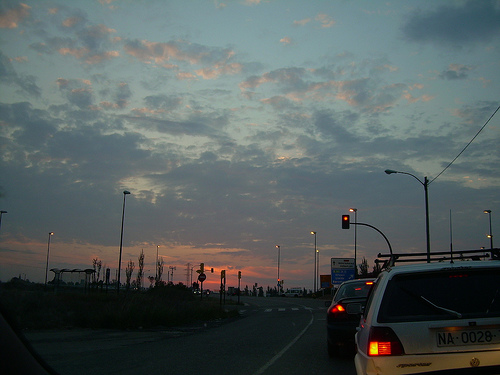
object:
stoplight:
[211, 268, 214, 274]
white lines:
[305, 307, 313, 310]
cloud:
[0, 0, 500, 293]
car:
[353, 260, 500, 375]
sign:
[198, 273, 206, 282]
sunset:
[163, 233, 263, 292]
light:
[343, 216, 349, 221]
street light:
[50, 232, 53, 236]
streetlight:
[123, 190, 130, 194]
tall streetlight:
[117, 194, 125, 294]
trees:
[155, 255, 164, 289]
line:
[252, 310, 314, 375]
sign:
[331, 258, 356, 285]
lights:
[310, 231, 315, 235]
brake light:
[368, 340, 391, 356]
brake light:
[331, 304, 345, 314]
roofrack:
[373, 248, 499, 265]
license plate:
[437, 328, 500, 347]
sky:
[0, 0, 500, 289]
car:
[325, 278, 379, 357]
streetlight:
[343, 224, 349, 229]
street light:
[310, 231, 315, 235]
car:
[192, 288, 201, 295]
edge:
[372, 272, 389, 320]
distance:
[12, 264, 342, 324]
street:
[28, 300, 339, 370]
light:
[385, 169, 396, 175]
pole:
[423, 176, 431, 263]